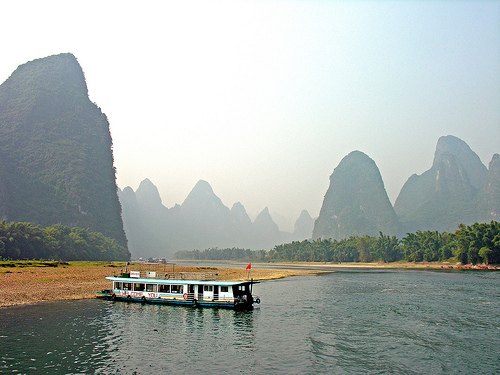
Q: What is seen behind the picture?
A: Mountain.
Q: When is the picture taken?
A: Daytime.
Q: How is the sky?
A: Cloudy.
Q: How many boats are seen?
A: One.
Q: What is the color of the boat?
A: Mainly white.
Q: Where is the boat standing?
A: In the water.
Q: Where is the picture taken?
A: Over the water.